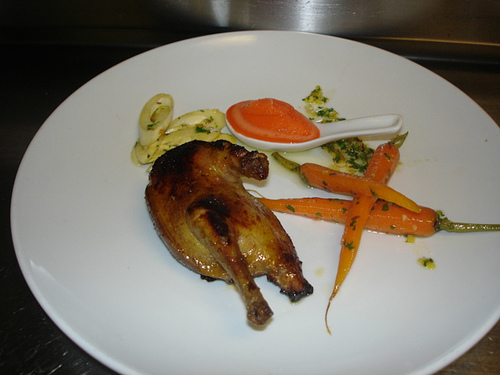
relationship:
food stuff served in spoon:
[231, 100, 321, 149] [231, 130, 313, 167]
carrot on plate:
[316, 192, 437, 234] [377, 289, 472, 321]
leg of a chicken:
[180, 206, 282, 329] [136, 140, 321, 332]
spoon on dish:
[225, 97, 400, 150] [10, 30, 498, 375]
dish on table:
[10, 30, 498, 375] [0, 9, 495, 369]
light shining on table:
[201, 8, 408, 30] [0, 9, 495, 369]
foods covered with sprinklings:
[129, 78, 497, 333] [278, 133, 414, 274]